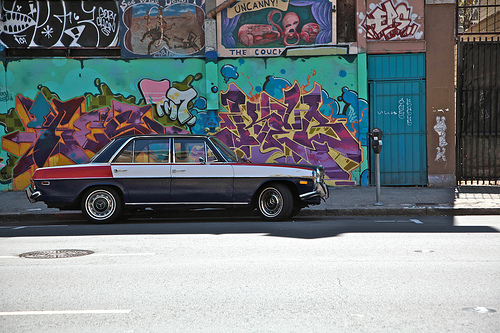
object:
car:
[27, 133, 330, 223]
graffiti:
[0, 57, 368, 186]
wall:
[0, 1, 371, 190]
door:
[366, 52, 430, 187]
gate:
[457, 1, 498, 185]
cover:
[20, 248, 97, 259]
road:
[0, 216, 499, 331]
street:
[0, 224, 499, 332]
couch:
[236, 23, 281, 48]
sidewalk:
[0, 188, 500, 225]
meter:
[368, 127, 384, 207]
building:
[0, 1, 458, 193]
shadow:
[0, 189, 499, 240]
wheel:
[256, 181, 294, 220]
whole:
[19, 245, 93, 260]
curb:
[0, 203, 500, 220]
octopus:
[266, 9, 311, 48]